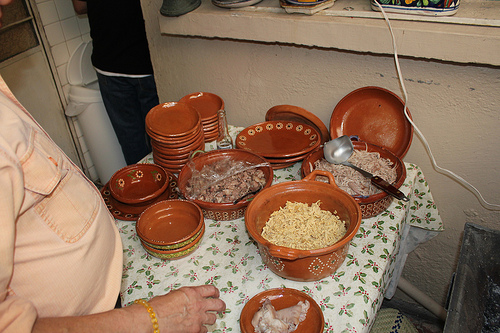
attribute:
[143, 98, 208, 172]
plates — brown, stack, small, ceramic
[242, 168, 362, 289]
bowl — brown, large, plain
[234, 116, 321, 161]
plate — brown, dinner, large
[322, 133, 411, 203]
spoon — large, serving spoon, laying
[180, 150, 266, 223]
dish — brown, large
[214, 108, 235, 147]
bottle — glass, clear, empty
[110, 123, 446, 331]
tablecloth — christmas themed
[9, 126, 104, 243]
pocket — light pink, breast pocket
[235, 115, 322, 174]
plates — big, stack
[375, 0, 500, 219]
cord — running, white, electrical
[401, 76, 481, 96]
marks — black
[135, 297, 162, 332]
band — yellow, orange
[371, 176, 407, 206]
handle — brown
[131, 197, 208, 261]
bowls — stack, small, brown, green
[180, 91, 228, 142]
saucers — stack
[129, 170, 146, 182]
print — floral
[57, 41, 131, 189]
garbage can — white, opened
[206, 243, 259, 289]
print — floral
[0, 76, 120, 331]
shirt — peach, orange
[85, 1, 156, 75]
shirt — black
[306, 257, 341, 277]
design — diamond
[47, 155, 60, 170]
hole — button hole